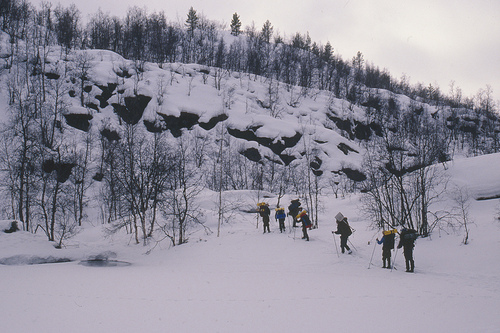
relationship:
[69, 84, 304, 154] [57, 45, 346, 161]
rocks beneath snow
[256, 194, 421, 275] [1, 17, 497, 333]
people in a journey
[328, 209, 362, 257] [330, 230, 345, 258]
person holding stick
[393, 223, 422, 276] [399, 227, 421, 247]
man carrying bag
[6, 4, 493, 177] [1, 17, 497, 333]
mountain full of snow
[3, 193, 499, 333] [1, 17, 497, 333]
ground has snow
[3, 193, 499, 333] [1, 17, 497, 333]
ground full of snow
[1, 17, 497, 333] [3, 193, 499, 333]
snow on ground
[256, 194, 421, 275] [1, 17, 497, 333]
people on snow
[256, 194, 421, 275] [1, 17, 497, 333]
people skiing uphill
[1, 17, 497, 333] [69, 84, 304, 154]
snow cover rocks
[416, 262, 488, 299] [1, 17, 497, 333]
marks on snow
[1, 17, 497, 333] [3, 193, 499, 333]
snow covered ground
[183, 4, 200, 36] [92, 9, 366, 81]
tree on top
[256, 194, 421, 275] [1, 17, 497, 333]
skiers traveling in snow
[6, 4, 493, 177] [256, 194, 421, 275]
mountainside in back of skiers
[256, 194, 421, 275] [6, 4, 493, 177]
skiers near hill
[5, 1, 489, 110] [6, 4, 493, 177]
evergreens lining mountain